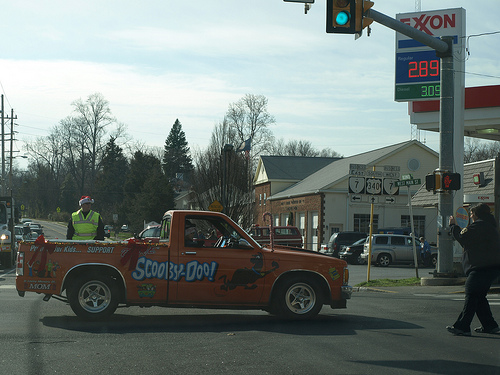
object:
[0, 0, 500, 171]
sky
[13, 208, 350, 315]
truck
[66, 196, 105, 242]
man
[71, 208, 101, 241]
safety vest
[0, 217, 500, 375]
ground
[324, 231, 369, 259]
car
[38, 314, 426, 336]
shadow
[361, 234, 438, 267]
car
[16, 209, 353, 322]
car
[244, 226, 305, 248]
car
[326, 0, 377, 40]
signal light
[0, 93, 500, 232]
trees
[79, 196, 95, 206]
hat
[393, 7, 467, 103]
sign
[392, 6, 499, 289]
gas station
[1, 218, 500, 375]
road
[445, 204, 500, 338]
person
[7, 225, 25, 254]
car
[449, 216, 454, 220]
camera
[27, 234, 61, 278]
bow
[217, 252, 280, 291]
scooby doo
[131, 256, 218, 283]
letter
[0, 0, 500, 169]
cloud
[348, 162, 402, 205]
sign